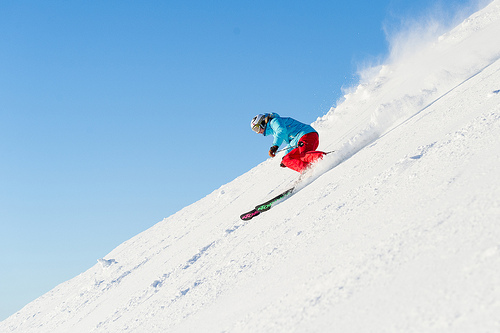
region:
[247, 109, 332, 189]
this is a person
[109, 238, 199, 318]
this is snow on the ground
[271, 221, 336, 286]
this is snow on the ground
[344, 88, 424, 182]
this is snow on the ground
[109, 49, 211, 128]
the sky is very clear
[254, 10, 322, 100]
the sky is very clear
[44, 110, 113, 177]
the sky is very clear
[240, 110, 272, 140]
head of a person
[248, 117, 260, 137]
goggle of a person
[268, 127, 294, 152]
arm of a person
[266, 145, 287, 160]
hand of a person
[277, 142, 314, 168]
leg of a person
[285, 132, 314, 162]
thigh of a person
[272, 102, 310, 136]
back of a person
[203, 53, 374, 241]
person on a ski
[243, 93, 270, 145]
person wearing a helmet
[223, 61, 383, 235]
person wearing a jacket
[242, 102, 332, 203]
skier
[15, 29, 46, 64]
white clouds in blue sky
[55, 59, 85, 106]
white clouds in blue sky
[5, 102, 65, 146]
white clouds in blue sky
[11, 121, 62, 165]
white clouds in blue sky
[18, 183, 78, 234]
white clouds in blue sky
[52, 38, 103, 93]
white clouds in blue sky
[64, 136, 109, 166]
white clouds in blue sky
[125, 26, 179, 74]
white clouds in blue sky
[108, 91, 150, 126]
white clouds in blue sky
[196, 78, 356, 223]
the woman is skiing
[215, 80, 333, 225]
the woman is skiing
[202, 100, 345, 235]
the woman is skiing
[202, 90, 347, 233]
the woman is skiing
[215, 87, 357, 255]
the woman is skiing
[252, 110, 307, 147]
the jacket is blue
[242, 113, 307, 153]
the jacket is blue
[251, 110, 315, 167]
the jacket is blue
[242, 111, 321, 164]
the jacket is blue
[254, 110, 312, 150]
the jacket is blue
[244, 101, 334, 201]
snow boarder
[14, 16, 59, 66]
white clouds in blue sky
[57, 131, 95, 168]
white clouds in blue sky